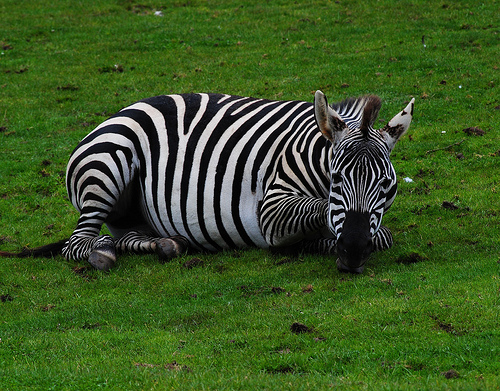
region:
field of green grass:
[0, 5, 496, 382]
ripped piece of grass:
[289, 320, 318, 335]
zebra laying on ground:
[65, 89, 417, 271]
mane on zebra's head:
[344, 93, 380, 131]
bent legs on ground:
[61, 228, 185, 267]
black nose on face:
[337, 210, 374, 271]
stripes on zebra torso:
[146, 98, 280, 247]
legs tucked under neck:
[264, 193, 394, 257]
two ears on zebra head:
[315, 88, 416, 140]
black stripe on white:
[149, 93, 180, 237]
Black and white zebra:
[0, 84, 418, 274]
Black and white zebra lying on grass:
[0, 92, 417, 274]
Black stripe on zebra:
[78, 121, 158, 234]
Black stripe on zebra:
[110, 107, 170, 239]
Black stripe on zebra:
[140, 94, 182, 240]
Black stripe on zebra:
[180, 93, 239, 250]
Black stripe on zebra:
[197, 97, 264, 255]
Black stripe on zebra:
[228, 100, 297, 245]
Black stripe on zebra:
[249, 101, 311, 198]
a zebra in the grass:
[34, 74, 420, 290]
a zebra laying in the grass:
[48, 69, 420, 296]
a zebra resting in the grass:
[48, 71, 408, 278]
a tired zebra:
[53, 78, 426, 285]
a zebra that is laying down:
[53, 76, 433, 286]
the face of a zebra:
[310, 79, 412, 275]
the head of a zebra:
[302, 76, 419, 271]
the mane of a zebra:
[330, 91, 383, 129]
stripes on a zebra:
[141, 110, 288, 230]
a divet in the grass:
[398, 243, 433, 273]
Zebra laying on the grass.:
[5, 42, 424, 272]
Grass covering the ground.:
[2, 0, 498, 389]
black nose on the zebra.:
[330, 199, 375, 281]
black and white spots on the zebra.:
[52, 85, 422, 275]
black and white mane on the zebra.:
[323, 83, 380, 138]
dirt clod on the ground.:
[284, 316, 319, 341]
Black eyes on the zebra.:
[327, 164, 392, 199]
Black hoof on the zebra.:
[83, 245, 118, 271]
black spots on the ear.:
[380, 90, 420, 152]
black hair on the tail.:
[4, 219, 83, 266]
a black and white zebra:
[16, 68, 422, 281]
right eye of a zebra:
[320, 167, 345, 192]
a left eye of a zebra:
[380, 172, 395, 187]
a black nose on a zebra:
[332, 210, 377, 255]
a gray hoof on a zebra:
[85, 250, 110, 266]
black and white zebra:
[167, 100, 267, 210]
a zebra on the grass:
[21, 75, 466, 300]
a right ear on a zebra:
[312, 86, 342, 138]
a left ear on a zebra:
[379, 93, 422, 143]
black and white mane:
[354, 93, 379, 128]